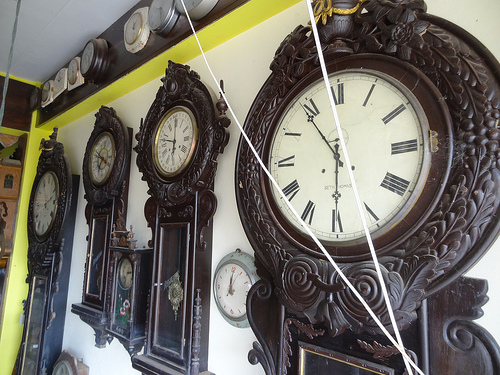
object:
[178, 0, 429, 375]
string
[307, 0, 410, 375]
string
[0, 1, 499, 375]
wall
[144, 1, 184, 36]
clock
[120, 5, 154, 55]
clock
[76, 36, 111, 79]
clock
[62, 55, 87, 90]
clock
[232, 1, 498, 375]
clock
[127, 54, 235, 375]
clock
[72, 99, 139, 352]
clock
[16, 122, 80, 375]
clock